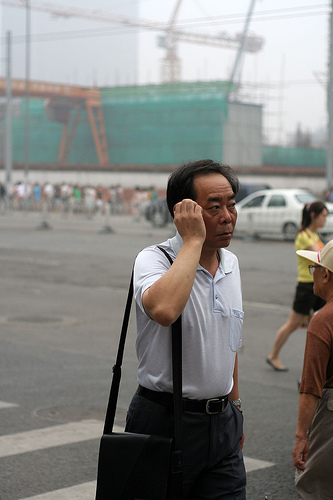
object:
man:
[121, 156, 245, 499]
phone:
[174, 206, 205, 224]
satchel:
[102, 244, 184, 499]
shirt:
[133, 228, 245, 400]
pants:
[124, 388, 251, 499]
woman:
[263, 202, 331, 374]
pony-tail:
[301, 202, 311, 234]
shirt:
[295, 230, 328, 284]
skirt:
[290, 278, 332, 317]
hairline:
[192, 173, 232, 181]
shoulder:
[135, 239, 170, 284]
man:
[291, 241, 333, 495]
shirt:
[298, 301, 332, 399]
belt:
[137, 384, 229, 413]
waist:
[135, 362, 236, 416]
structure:
[1, 77, 110, 165]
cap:
[295, 239, 333, 272]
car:
[231, 190, 332, 239]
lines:
[1, 400, 272, 499]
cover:
[11, 315, 61, 325]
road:
[1, 224, 331, 499]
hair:
[299, 199, 324, 230]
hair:
[166, 157, 241, 212]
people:
[8, 182, 163, 215]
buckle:
[205, 398, 222, 414]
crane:
[0, 2, 265, 175]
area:
[4, 191, 332, 499]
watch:
[232, 398, 241, 408]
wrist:
[228, 396, 244, 412]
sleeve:
[299, 328, 327, 402]